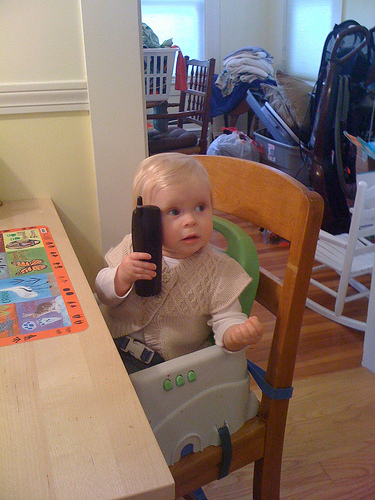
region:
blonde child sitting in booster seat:
[99, 143, 276, 429]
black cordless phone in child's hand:
[125, 192, 172, 302]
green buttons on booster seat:
[156, 364, 201, 396]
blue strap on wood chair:
[248, 359, 297, 405]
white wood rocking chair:
[304, 181, 373, 322]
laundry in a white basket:
[139, 20, 177, 106]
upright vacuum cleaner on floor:
[300, 15, 370, 234]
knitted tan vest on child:
[98, 230, 248, 361]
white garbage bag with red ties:
[206, 125, 263, 164]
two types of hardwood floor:
[306, 342, 351, 405]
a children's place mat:
[2, 219, 89, 362]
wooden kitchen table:
[4, 191, 176, 496]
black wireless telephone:
[127, 195, 164, 302]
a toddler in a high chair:
[85, 145, 268, 475]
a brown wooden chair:
[148, 143, 318, 497]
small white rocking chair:
[286, 169, 373, 336]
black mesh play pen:
[300, 16, 373, 203]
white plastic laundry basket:
[136, 44, 189, 105]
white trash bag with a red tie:
[203, 119, 267, 170]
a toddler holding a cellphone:
[94, 150, 266, 372]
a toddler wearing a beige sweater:
[90, 149, 265, 371]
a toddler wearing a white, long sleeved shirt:
[93, 151, 264, 374]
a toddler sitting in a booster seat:
[89, 150, 262, 472]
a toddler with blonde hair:
[92, 150, 265, 372]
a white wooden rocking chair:
[306, 181, 374, 331]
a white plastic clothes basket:
[140, 46, 178, 103]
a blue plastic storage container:
[251, 126, 308, 181]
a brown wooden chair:
[145, 54, 215, 154]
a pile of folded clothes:
[214, 44, 276, 96]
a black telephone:
[122, 188, 169, 302]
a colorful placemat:
[0, 226, 80, 343]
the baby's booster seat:
[133, 208, 275, 461]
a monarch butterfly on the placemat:
[6, 252, 51, 276]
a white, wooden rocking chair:
[309, 172, 373, 342]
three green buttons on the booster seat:
[156, 368, 202, 394]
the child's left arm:
[212, 257, 267, 360]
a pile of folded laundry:
[216, 39, 273, 116]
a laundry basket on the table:
[140, 20, 189, 101]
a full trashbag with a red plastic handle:
[196, 122, 262, 177]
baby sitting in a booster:
[92, 153, 274, 465]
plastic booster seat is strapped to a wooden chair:
[170, 153, 322, 499]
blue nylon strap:
[245, 358, 297, 400]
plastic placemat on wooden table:
[1, 226, 88, 355]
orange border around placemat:
[37, 225, 88, 338]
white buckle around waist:
[115, 334, 163, 367]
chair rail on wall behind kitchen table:
[0, 81, 91, 118]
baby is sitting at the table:
[94, 152, 269, 375]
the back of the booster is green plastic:
[209, 213, 264, 315]